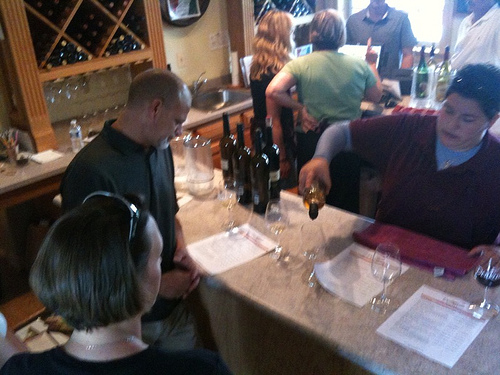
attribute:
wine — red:
[457, 237, 498, 334]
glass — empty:
[363, 240, 404, 312]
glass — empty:
[291, 214, 335, 290]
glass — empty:
[261, 195, 297, 272]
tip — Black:
[307, 200, 333, 230]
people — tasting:
[0, 2, 496, 373]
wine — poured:
[248, 139, 390, 258]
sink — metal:
[193, 80, 255, 113]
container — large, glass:
[171, 117, 261, 175]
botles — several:
[258, 125, 282, 199]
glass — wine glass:
[349, 222, 421, 332]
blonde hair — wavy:
[248, 2, 296, 88]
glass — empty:
[366, 231, 404, 327]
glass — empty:
[469, 241, 498, 323]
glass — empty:
[291, 216, 324, 293]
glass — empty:
[259, 196, 289, 263]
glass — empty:
[215, 172, 245, 244]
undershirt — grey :
[311, 118, 356, 161]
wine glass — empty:
[327, 225, 448, 352]